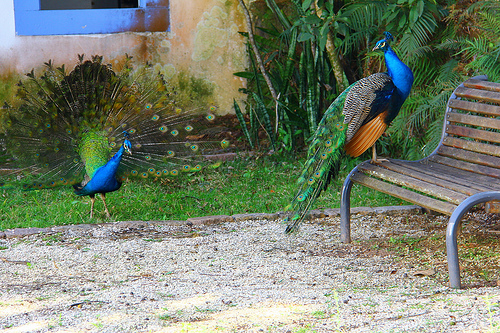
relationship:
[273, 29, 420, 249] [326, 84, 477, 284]
peacock standing bench